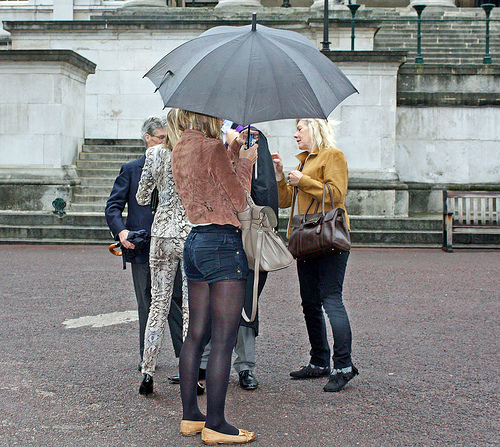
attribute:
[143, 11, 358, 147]
umbrella — large, black, open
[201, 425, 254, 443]
shoe — brown, tan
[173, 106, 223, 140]
hair — blonde, light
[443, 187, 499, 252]
bench — wooden, small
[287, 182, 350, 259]
purse — large, brown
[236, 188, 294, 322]
handbag — grey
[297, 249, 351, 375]
pants — blue, showing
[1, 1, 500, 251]
building — white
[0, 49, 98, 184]
wall — white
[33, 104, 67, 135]
brick — white, small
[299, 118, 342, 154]
hair — blonde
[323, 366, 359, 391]
shoe — black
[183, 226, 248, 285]
shorts — blue, denim